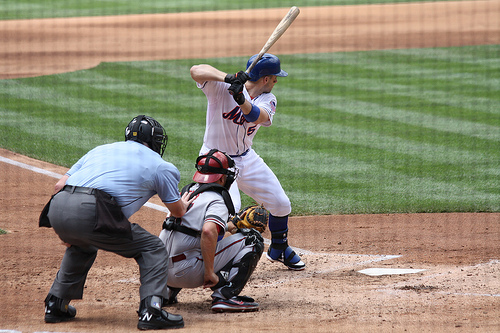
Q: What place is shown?
A: It is a field.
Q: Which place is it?
A: It is a field.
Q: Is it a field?
A: Yes, it is a field.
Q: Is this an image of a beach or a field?
A: It is showing a field.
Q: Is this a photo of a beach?
A: No, the picture is showing a field.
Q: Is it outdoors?
A: Yes, it is outdoors.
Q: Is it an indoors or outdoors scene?
A: It is outdoors.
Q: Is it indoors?
A: No, it is outdoors.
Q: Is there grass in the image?
A: Yes, there is grass.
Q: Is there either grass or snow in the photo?
A: Yes, there is grass.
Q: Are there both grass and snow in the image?
A: No, there is grass but no snow.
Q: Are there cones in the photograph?
A: No, there are no cones.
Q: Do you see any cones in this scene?
A: No, there are no cones.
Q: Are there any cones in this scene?
A: No, there are no cones.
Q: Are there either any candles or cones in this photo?
A: No, there are no cones or candles.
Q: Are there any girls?
A: No, there are no girls.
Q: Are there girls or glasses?
A: No, there are no girls or glasses.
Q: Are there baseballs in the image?
A: Yes, there is a baseball.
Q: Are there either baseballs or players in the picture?
A: Yes, there is a baseball.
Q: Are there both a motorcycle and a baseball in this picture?
A: No, there is a baseball but no motorcycles.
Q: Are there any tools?
A: No, there are no tools.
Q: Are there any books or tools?
A: No, there are no tools or books.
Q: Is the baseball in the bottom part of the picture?
A: Yes, the baseball is in the bottom of the image.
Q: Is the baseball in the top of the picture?
A: No, the baseball is in the bottom of the image.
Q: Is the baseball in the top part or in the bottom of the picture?
A: The baseball is in the bottom of the image.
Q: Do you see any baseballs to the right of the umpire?
A: Yes, there is a baseball to the right of the umpire.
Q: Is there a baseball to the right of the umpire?
A: Yes, there is a baseball to the right of the umpire.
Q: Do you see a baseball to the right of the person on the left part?
A: Yes, there is a baseball to the right of the umpire.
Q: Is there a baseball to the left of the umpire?
A: No, the baseball is to the right of the umpire.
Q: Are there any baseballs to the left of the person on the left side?
A: No, the baseball is to the right of the umpire.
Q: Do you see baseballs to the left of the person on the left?
A: No, the baseball is to the right of the umpire.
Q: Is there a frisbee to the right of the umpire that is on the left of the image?
A: No, there is a baseball to the right of the umpire.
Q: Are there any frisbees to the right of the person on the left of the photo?
A: No, there is a baseball to the right of the umpire.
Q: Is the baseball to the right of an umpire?
A: Yes, the baseball is to the right of an umpire.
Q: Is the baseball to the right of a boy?
A: No, the baseball is to the right of an umpire.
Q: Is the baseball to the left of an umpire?
A: No, the baseball is to the right of an umpire.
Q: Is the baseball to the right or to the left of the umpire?
A: The baseball is to the right of the umpire.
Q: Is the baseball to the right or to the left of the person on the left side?
A: The baseball is to the right of the umpire.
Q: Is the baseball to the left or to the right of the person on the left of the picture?
A: The baseball is to the right of the umpire.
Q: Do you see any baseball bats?
A: Yes, there is a baseball bat.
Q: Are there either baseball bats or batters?
A: Yes, there is a baseball bat.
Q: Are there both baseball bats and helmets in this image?
A: Yes, there are both a baseball bat and a helmet.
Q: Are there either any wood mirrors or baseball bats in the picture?
A: Yes, there is a wood baseball bat.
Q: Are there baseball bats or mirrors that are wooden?
A: Yes, the baseball bat is wooden.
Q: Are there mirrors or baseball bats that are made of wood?
A: Yes, the baseball bat is made of wood.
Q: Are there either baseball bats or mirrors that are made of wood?
A: Yes, the baseball bat is made of wood.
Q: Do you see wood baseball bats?
A: Yes, there is a wood baseball bat.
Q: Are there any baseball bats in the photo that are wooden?
A: Yes, there is a baseball bat that is wooden.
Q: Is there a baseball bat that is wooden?
A: Yes, there is a baseball bat that is wooden.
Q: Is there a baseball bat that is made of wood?
A: Yes, there is a baseball bat that is made of wood.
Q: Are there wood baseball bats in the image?
A: Yes, there is a baseball bat that is made of wood.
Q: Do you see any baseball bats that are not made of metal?
A: Yes, there is a baseball bat that is made of wood.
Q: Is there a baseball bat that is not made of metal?
A: Yes, there is a baseball bat that is made of wood.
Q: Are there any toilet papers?
A: No, there are no toilet papers.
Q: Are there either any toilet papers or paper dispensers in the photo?
A: No, there are no toilet papers or paper dispensers.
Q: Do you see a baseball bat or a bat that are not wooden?
A: No, there is a baseball bat but it is wooden.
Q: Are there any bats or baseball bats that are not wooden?
A: No, there is a baseball bat but it is wooden.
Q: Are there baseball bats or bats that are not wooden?
A: No, there is a baseball bat but it is wooden.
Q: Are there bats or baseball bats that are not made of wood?
A: No, there is a baseball bat but it is made of wood.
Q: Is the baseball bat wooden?
A: Yes, the baseball bat is wooden.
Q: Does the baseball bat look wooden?
A: Yes, the baseball bat is wooden.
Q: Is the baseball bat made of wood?
A: Yes, the baseball bat is made of wood.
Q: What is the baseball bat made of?
A: The baseball bat is made of wood.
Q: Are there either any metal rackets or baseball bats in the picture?
A: No, there is a baseball bat but it is wooden.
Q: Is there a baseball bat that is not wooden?
A: No, there is a baseball bat but it is wooden.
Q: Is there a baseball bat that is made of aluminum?
A: No, there is a baseball bat but it is made of wood.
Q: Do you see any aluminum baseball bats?
A: No, there is a baseball bat but it is made of wood.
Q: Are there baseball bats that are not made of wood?
A: No, there is a baseball bat but it is made of wood.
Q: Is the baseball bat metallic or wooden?
A: The baseball bat is wooden.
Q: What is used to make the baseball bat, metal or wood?
A: The baseball bat is made of wood.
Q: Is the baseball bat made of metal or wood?
A: The baseball bat is made of wood.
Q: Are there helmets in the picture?
A: Yes, there is a helmet.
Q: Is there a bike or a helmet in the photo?
A: Yes, there is a helmet.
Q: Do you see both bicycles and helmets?
A: No, there is a helmet but no bikes.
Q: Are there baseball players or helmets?
A: Yes, there is a baseball helmet.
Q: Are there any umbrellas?
A: No, there are no umbrellas.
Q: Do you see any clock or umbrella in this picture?
A: No, there are no umbrellas or clocks.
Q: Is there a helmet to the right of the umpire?
A: Yes, there is a helmet to the right of the umpire.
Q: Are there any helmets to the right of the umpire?
A: Yes, there is a helmet to the right of the umpire.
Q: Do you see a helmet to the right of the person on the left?
A: Yes, there is a helmet to the right of the umpire.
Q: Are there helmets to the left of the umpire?
A: No, the helmet is to the right of the umpire.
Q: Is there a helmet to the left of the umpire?
A: No, the helmet is to the right of the umpire.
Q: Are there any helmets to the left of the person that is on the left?
A: No, the helmet is to the right of the umpire.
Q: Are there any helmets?
A: Yes, there is a helmet.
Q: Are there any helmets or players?
A: Yes, there is a helmet.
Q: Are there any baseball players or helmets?
A: Yes, there is a baseball helmet.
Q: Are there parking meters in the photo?
A: No, there are no parking meters.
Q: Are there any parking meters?
A: No, there are no parking meters.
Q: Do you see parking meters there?
A: No, there are no parking meters.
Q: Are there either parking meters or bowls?
A: No, there are no parking meters or bowls.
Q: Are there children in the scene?
A: No, there are no children.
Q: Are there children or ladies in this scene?
A: No, there are no children or ladies.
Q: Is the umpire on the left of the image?
A: Yes, the umpire is on the left of the image.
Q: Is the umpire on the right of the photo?
A: No, the umpire is on the left of the image.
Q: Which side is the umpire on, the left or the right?
A: The umpire is on the left of the image.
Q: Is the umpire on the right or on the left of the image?
A: The umpire is on the left of the image.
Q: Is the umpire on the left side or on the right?
A: The umpire is on the left of the image.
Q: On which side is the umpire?
A: The umpire is on the left of the image.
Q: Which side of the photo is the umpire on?
A: The umpire is on the left of the image.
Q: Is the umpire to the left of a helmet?
A: Yes, the umpire is to the left of a helmet.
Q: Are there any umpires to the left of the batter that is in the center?
A: Yes, there is an umpire to the left of the batter.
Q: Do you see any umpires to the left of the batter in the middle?
A: Yes, there is an umpire to the left of the batter.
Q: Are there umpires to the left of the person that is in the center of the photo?
A: Yes, there is an umpire to the left of the batter.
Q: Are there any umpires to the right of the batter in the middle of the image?
A: No, the umpire is to the left of the batter.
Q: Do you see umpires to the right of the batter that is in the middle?
A: No, the umpire is to the left of the batter.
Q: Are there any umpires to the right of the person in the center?
A: No, the umpire is to the left of the batter.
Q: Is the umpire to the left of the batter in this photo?
A: Yes, the umpire is to the left of the batter.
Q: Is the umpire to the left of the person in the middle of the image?
A: Yes, the umpire is to the left of the batter.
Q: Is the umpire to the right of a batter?
A: No, the umpire is to the left of a batter.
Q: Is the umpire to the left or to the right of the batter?
A: The umpire is to the left of the batter.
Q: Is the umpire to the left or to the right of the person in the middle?
A: The umpire is to the left of the batter.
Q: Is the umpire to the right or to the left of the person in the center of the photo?
A: The umpire is to the left of the batter.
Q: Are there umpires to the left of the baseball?
A: Yes, there is an umpire to the left of the baseball.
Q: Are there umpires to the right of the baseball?
A: No, the umpire is to the left of the baseball.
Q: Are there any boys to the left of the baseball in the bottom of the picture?
A: No, there is an umpire to the left of the baseball.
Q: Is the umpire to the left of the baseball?
A: Yes, the umpire is to the left of the baseball.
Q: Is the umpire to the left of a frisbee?
A: No, the umpire is to the left of the baseball.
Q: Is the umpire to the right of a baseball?
A: No, the umpire is to the left of a baseball.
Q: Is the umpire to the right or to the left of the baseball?
A: The umpire is to the left of the baseball.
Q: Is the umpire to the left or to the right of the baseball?
A: The umpire is to the left of the baseball.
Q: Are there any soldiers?
A: No, there are no soldiers.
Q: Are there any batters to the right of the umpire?
A: Yes, there is a batter to the right of the umpire.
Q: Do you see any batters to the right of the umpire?
A: Yes, there is a batter to the right of the umpire.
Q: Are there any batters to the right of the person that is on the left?
A: Yes, there is a batter to the right of the umpire.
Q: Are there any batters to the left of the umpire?
A: No, the batter is to the right of the umpire.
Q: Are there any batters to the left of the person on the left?
A: No, the batter is to the right of the umpire.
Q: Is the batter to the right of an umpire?
A: Yes, the batter is to the right of an umpire.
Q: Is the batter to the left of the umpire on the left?
A: No, the batter is to the right of the umpire.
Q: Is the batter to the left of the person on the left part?
A: No, the batter is to the right of the umpire.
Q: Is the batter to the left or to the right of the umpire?
A: The batter is to the right of the umpire.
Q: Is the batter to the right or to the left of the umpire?
A: The batter is to the right of the umpire.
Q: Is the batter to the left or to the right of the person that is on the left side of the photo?
A: The batter is to the right of the umpire.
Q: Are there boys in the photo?
A: No, there are no boys.